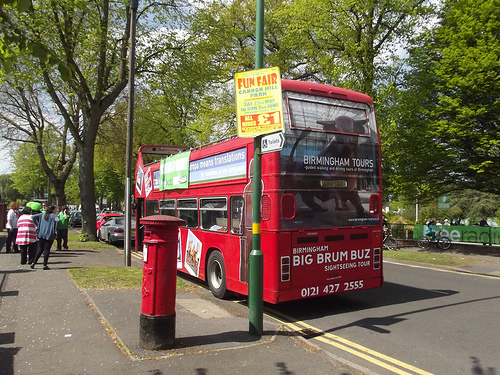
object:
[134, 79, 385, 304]
bus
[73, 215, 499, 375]
street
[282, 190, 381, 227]
windshield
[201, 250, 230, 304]
wheel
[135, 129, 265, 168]
sitting area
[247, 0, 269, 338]
pole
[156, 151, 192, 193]
banner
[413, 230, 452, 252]
bike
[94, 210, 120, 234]
car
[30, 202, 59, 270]
man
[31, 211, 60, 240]
sweater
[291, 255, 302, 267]
letter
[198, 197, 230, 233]
window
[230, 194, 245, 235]
window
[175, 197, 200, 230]
window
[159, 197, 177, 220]
window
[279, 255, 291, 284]
light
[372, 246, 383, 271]
light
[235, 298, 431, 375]
lines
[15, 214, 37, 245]
sweater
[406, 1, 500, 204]
tree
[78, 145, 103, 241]
tree trunk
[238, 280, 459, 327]
shadow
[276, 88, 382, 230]
advertisements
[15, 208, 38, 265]
person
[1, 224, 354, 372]
sidewalk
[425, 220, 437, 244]
person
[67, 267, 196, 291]
grass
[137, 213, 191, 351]
trash bin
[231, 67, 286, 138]
sign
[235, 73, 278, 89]
"fun fair"